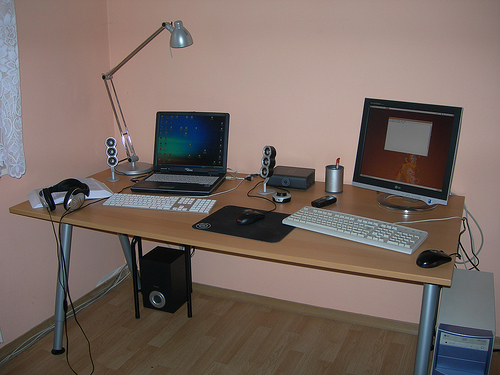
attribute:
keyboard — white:
[281, 205, 429, 254]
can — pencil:
[325, 163, 347, 194]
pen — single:
[332, 155, 342, 166]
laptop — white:
[284, 203, 434, 258]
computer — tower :
[421, 272, 498, 373]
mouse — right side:
[418, 237, 454, 269]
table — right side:
[57, 117, 462, 367]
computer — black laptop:
[127, 100, 232, 197]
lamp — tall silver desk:
[94, 14, 194, 180]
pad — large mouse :
[188, 202, 296, 249]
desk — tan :
[4, 141, 469, 361]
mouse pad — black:
[192, 202, 299, 246]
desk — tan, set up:
[7, 160, 465, 372]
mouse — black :
[235, 205, 259, 229]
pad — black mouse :
[214, 202, 281, 243]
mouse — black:
[274, 192, 294, 204]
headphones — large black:
[37, 177, 92, 216]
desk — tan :
[8, 147, 468, 286]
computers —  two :
[102, 94, 464, 264]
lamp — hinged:
[123, 7, 202, 85]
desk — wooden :
[9, 159, 464, 287]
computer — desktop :
[282, 98, 462, 267]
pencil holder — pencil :
[323, 162, 347, 195]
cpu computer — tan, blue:
[428, 267, 498, 373]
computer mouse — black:
[415, 243, 455, 271]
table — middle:
[31, 139, 461, 371]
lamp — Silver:
[102, 21, 192, 181]